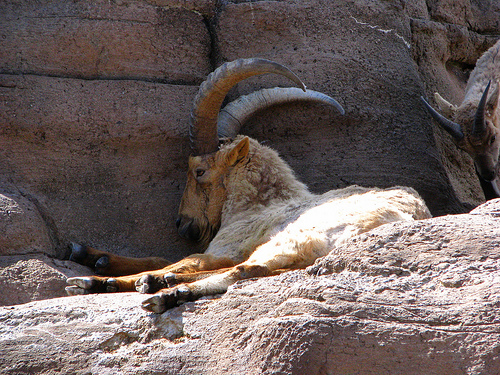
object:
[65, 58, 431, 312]
animal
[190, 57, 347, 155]
horns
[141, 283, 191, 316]
rear foot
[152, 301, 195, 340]
shadow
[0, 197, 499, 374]
cliff face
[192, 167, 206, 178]
eye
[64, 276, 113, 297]
hoof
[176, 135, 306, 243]
head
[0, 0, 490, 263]
wall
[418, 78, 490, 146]
horns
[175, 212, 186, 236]
nose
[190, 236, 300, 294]
legs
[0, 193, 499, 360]
light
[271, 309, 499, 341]
grooves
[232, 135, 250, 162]
ears